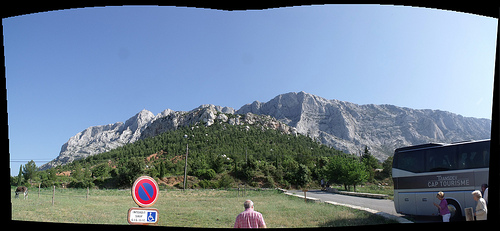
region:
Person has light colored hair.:
[432, 185, 450, 207]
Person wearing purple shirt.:
[432, 193, 452, 213]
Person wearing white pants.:
[437, 211, 454, 229]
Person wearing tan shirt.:
[473, 192, 489, 223]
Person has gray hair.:
[469, 189, 485, 206]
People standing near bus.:
[424, 178, 499, 227]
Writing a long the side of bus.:
[416, 170, 471, 190]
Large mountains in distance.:
[73, 99, 423, 154]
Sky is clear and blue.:
[131, 39, 339, 87]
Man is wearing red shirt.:
[238, 216, 266, 228]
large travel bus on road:
[389, 136, 491, 225]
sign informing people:
[128, 175, 159, 225]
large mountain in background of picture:
[51, 90, 489, 164]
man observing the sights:
[236, 195, 266, 227]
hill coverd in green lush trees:
[12, 123, 391, 190]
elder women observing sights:
[435, 190, 489, 222]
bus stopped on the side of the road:
[395, 139, 495, 222]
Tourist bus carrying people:
[392, 137, 489, 225]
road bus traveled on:
[276, 186, 416, 226]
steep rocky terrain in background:
[56, 89, 491, 161]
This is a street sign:
[114, 154, 196, 226]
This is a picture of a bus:
[357, 154, 496, 217]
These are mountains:
[93, 73, 415, 224]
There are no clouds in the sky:
[102, 55, 129, 96]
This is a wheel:
[444, 199, 459, 205]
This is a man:
[233, 191, 264, 226]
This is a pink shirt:
[235, 205, 255, 222]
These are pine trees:
[180, 150, 397, 222]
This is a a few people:
[414, 202, 489, 222]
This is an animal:
[15, 182, 73, 202]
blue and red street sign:
[130, 174, 161, 204]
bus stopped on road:
[387, 145, 493, 218]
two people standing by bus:
[432, 186, 487, 217]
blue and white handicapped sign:
[148, 212, 156, 220]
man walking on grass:
[228, 192, 264, 228]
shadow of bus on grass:
[316, 210, 399, 224]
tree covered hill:
[49, 120, 371, 183]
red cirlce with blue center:
[129, 175, 159, 203]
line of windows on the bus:
[391, 147, 499, 175]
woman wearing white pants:
[436, 187, 451, 220]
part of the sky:
[272, 37, 310, 64]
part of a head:
[241, 190, 260, 215]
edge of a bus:
[420, 124, 445, 150]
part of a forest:
[238, 113, 275, 147]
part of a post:
[181, 169, 196, 190]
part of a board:
[128, 175, 153, 204]